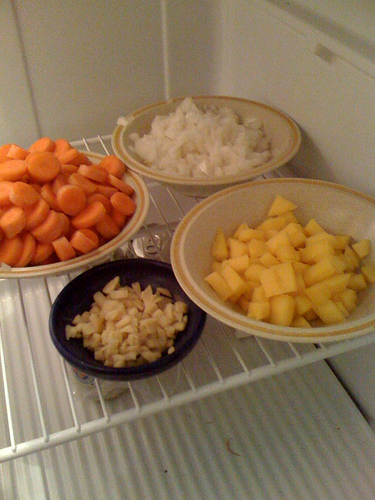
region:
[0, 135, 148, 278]
Carrots are in a bowl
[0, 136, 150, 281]
Carrots are in a white bowl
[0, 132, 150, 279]
Sliced carrots are in a bowl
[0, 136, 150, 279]
Sliced carrots are in a white bowl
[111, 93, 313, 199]
Onions are in a bowl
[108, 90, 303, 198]
Onions are in a white bowl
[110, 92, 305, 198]
Chopped onions in a bowl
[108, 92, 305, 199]
Chopped onions in a white bowl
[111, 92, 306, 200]
White onions in a bowl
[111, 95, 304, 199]
White onions in a white bowl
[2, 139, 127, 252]
The sliced carrots in the bowl.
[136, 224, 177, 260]
The can on the bottom shelf.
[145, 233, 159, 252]
The tab on the can.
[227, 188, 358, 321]
The yellow chopped product on the right.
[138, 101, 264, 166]
The chopped white item in the bowl.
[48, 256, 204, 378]
The dark blue bowl on the shelf.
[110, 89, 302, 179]
The bowl in the top right corner.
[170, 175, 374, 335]
The bowl in the bottom right hand corner.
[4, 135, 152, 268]
The bowl in the top left corner.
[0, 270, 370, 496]
The shelf on the bottom of the fridge.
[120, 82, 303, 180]
Bowl of food in fridge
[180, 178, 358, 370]
Bowl of food in fridge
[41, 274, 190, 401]
Bowl of food in fridge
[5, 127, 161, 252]
Bowl of food in fridge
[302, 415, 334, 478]
Small dips in the plastic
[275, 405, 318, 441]
Small dips in the plastic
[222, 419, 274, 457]
Small dips in the plastic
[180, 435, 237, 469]
Small dips in the plastic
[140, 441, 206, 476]
Small dips in the plastic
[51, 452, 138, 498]
Small dips in the plastic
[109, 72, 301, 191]
A bowl of chopped onions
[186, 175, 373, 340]
A bowl of chopped potatoes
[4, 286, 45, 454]
A white metal refrigerator rack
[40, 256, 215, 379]
A bowl of chopped garlic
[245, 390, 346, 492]
The bottom shelf of a refrigerator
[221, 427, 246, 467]
Crumbs on the bottom shelf of a refrigerator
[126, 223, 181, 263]
The silver top of a pop can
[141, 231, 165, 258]
A metal pull tab on a pop can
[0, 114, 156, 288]
Chopped orange carrots in a bowl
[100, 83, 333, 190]
Chopped onions in a white and gold striped bowl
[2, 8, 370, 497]
inside of a refrigerator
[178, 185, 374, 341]
bowl of cut up pineapple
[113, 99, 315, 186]
bowl of cut up carrots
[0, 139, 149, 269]
bowl of cut up carrots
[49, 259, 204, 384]
bowl of minced garlic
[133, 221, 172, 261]
top of a soda or beer can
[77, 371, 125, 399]
package of cheese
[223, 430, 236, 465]
debris on bottom of fridge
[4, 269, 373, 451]
wire shelving for storage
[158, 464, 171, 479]
piece of debris on bottom shelf